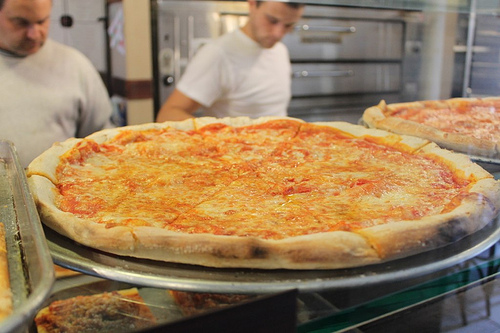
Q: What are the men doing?
A: Making pizzas.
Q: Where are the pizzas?
A: On shelves.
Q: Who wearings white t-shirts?
A: The men.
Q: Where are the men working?
A: Pizza kitchen.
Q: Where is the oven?
A: Behind the man on the right.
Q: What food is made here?
A: Pizza.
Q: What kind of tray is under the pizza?
A: Silver metal.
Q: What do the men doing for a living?
A: Cook.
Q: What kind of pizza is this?
A: Cheese.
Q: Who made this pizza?
A: Cook.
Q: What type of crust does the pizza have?
A: Thick.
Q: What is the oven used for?
A: Cook.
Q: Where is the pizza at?
A: Restaurant.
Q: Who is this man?
A: Cook.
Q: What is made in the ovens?
A: Pizza.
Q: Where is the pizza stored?
A: Display shelf.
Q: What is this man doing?
A: Preparing pizza.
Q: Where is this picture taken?
A: Pizzeria.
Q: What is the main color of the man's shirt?
A: White.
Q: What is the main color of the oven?
A: Gray.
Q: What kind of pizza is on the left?
A: Cheese.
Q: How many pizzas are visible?
A: Two.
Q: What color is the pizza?
A: Orange.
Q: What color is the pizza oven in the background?
A: Silver.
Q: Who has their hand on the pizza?
A: No one.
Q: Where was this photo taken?
A: Pizza parlor.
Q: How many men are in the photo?
A: Two.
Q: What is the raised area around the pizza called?
A: Crust.